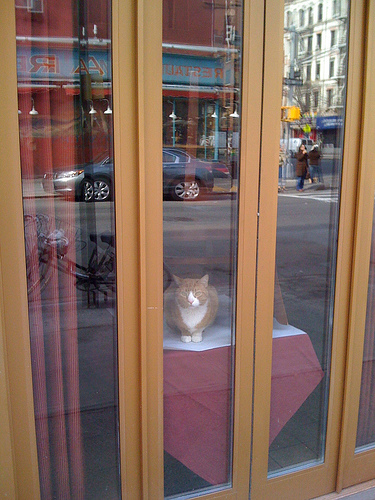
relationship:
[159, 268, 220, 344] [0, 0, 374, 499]
cat in window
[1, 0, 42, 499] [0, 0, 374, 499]
frame on window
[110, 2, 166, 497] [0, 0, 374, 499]
frame on window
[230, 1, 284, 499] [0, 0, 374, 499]
frame on window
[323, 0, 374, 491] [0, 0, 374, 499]
frame on window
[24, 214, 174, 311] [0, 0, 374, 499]
bicycle reflected in window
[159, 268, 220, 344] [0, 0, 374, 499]
cat looking out window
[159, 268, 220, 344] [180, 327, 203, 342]
cat has legs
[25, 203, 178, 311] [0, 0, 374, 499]
bicycle reflected in window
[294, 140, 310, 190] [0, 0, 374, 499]
person reflected in window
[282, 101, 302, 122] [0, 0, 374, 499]
traffic light reflected in window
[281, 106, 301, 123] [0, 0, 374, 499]
sign reflected in window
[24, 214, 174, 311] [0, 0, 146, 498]
bicycle reflected in window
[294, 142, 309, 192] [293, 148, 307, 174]
person wearing jacket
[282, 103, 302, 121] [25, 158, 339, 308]
sign on street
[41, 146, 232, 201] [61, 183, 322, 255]
car parked on road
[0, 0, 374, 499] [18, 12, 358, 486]
frame on door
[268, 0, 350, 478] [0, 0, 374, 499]
glass in window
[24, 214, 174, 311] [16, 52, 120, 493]
bicycle reflected in glass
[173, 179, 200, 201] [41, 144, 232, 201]
rim on car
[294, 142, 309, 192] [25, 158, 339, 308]
person standing on street